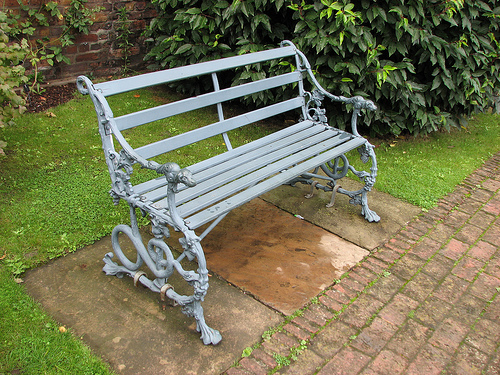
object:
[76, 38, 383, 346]
bench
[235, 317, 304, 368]
moss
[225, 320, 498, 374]
bricks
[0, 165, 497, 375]
ground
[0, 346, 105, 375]
grass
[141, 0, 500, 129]
bush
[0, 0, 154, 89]
wall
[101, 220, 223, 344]
legs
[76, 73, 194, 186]
arms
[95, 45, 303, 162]
back